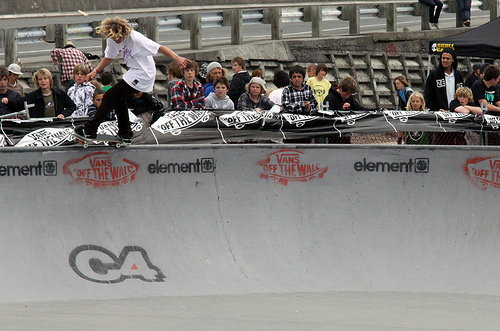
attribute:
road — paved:
[8, 0, 493, 60]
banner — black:
[5, 105, 498, 148]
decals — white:
[13, 122, 79, 154]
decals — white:
[159, 98, 213, 143]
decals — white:
[217, 100, 276, 132]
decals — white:
[284, 102, 326, 137]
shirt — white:
[103, 29, 163, 94]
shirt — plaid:
[51, 48, 91, 81]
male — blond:
[68, 14, 201, 146]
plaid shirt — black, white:
[167, 77, 206, 108]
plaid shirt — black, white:
[279, 85, 317, 112]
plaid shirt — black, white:
[48, 46, 86, 65]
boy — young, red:
[167, 54, 207, 114]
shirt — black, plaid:
[167, 78, 208, 114]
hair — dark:
[134, 39, 204, 80]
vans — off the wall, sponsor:
[228, 146, 376, 217]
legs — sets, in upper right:
[76, 75, 144, 144]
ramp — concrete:
[165, 187, 379, 293]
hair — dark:
[314, 60, 330, 75]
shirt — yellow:
[308, 76, 332, 111]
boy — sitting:
[101, 22, 128, 37]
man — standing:
[424, 49, 469, 132]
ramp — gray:
[171, 126, 391, 248]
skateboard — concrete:
[48, 104, 152, 161]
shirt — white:
[444, 70, 457, 101]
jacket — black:
[424, 65, 466, 111]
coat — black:
[422, 61, 472, 113]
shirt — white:
[443, 73, 455, 106]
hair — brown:
[91, 15, 132, 40]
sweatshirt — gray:
[204, 92, 237, 112]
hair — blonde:
[408, 90, 426, 113]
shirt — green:
[401, 105, 434, 148]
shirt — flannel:
[47, 44, 98, 83]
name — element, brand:
[141, 151, 223, 180]